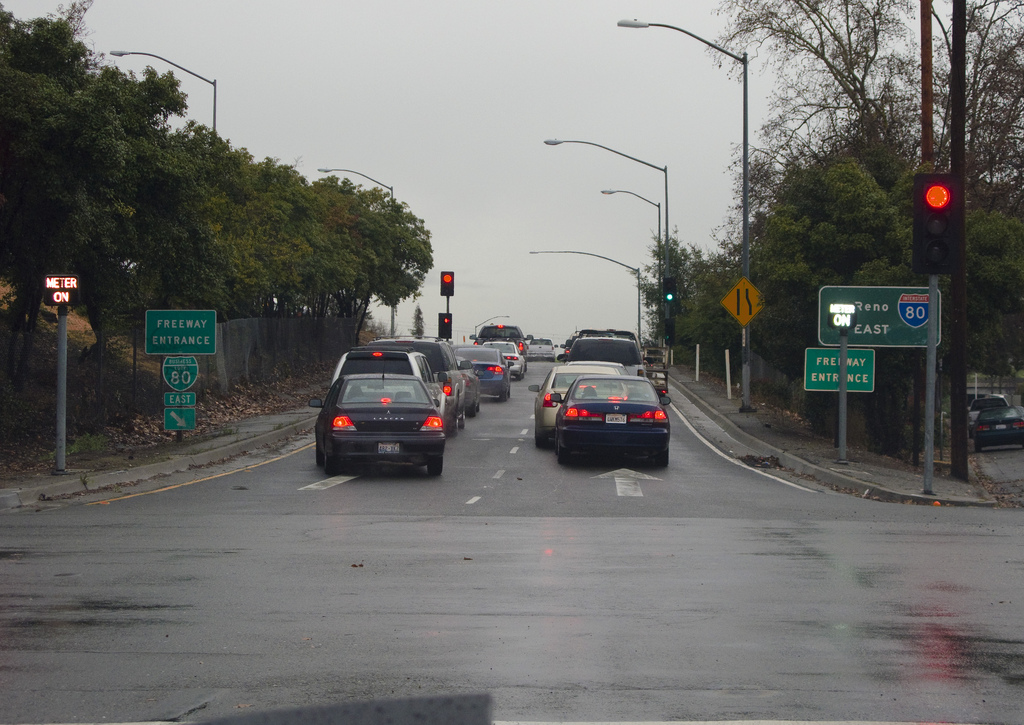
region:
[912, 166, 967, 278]
an electric traffic signal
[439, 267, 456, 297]
an electric traffic signal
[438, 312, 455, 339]
an electric traffic signal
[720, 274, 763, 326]
a lane merge traffic sign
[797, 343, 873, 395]
a freeway entrance traffic sign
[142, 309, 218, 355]
a freeway entrance sign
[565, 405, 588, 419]
a lit car brake light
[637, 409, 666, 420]
a lit car brake light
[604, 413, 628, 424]
a white license plate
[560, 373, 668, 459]
Blue Honda bringing up the rear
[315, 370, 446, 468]
Blue Mitsubishi Lancer at the end of the line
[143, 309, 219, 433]
Green Sign announcing a freeway entrance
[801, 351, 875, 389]
Sign on the right side of the road for a freeway entrance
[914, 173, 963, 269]
Street light on red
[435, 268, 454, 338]
Freeway merging light on red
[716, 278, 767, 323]
Yellow caution sign saying be prepared to merge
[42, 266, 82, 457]
Sign letting people know the meter light is running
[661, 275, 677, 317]
Green light on the right side meter light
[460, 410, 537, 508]
white dashed stripe on road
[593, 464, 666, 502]
white arrow on the road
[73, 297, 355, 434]
short fence along the road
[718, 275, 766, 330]
yellow diamond shaped traffic sign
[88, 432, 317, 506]
solid yellow line on road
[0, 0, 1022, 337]
light gray overcast sky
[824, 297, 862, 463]
green lit meter notice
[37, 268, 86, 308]
red lit meter notice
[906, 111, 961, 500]
traffic light on a metal pole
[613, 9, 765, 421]
street light and pole on a curb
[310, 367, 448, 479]
small dark black car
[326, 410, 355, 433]
small square red light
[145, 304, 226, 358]
large rectangular green sign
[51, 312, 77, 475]
short round metal pole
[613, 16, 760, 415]
tall large metal street light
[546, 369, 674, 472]
small metal blue car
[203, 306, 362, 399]
long metal grey fence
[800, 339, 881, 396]
large square green sign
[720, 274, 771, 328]
small metal yellow sign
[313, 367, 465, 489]
A car on a street.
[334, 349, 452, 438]
A car on a street.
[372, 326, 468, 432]
A car on a street.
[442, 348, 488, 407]
A car on a street.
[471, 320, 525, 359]
A car on a street.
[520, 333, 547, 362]
A car on a street.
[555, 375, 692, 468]
A car on a street.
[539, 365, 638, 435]
A car on a street.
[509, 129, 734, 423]
Street lights over street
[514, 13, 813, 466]
Street lights over pole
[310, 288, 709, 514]
Cars on the road